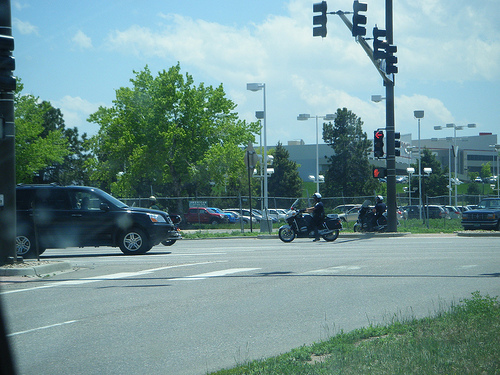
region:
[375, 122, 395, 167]
a red street light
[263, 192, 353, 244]
a person driving a motorcycle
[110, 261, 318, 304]
white street lines in the pavement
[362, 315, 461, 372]
grass on the side of the road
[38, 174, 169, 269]
a dark SUV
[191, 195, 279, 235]
a parking lot in the background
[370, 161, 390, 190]
a don't walk sign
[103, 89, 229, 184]
a bushy tree in the background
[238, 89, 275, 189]
parklot light poles in the back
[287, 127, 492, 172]
a large building in the background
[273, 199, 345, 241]
a black motorcycle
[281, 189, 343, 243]
a man on a motorcycle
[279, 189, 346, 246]
a police officer on a motorcycle in intersection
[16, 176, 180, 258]
a black moving SUV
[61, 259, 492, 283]
a marked pedestrian crosswalk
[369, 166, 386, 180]
a do not walk sign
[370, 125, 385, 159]
an electric traffic signal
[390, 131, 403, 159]
an electric traffic signal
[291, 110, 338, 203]
a tall white overhead light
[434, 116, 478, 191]
a tall white overhead light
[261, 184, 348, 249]
the police officer in the street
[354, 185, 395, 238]
the police officer on the black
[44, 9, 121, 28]
the clear blue sky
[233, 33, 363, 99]
the clouds in the sky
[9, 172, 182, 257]
the car in the street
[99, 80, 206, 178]
the trees with green leaves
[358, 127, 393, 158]
the traffic light on the pole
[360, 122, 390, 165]
the light is red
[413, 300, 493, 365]
the grass beside the street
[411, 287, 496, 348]
the grass is uncut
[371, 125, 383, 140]
The red arrow on the traffic light.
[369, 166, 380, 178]
The red hand on the crossing light.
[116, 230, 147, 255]
The front tire of the black vehicle on the left.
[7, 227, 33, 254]
The back tire of the vehicle on the left.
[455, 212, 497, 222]
The front headlights of the truck on the right.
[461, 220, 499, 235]
The front fender of the vehicle on the right.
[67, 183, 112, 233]
The passenger door of the vehicle on the left.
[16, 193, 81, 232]
The back door of the vehicle on the left.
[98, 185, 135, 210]
The front window of the vehicle on the left.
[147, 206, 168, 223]
The front headlight of the vehicle on the left.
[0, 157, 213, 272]
The car is on the street.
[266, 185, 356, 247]
A motorcycle goes in the other direction.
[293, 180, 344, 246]
A police offer rides the motorcycle.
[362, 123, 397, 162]
The traffic light is red.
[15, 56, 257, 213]
Trees are next to the street.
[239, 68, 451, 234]
Parking lots lights are next to the street.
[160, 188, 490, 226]
Cars are parked in a lot.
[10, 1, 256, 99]
The sky is blue.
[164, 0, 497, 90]
Clouds are in the sky.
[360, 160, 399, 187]
A no walking signal is lit up.